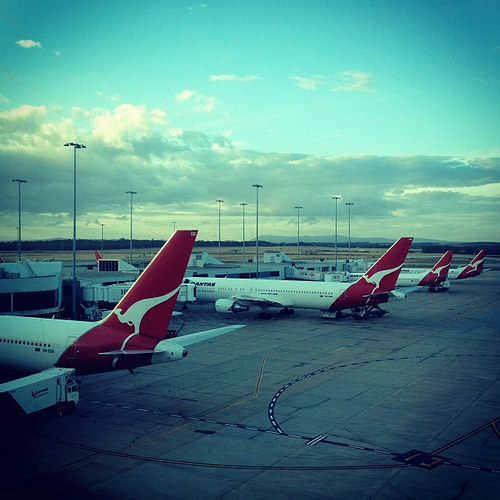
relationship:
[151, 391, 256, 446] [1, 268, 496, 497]
line on tarmac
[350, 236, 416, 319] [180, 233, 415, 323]
tail on plane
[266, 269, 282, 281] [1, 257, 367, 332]
window on building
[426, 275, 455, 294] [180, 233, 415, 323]
truck by plane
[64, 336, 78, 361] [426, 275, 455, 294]
door by truck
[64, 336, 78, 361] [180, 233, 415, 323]
door on plane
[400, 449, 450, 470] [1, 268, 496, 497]
box on tarmac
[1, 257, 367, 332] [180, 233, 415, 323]
building by plane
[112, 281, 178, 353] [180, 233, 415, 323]
logo on plane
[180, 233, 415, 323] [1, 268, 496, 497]
plane on tarmac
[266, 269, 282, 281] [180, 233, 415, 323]
window by plane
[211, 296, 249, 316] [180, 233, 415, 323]
engine on plane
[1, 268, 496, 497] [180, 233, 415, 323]
tarmac with plane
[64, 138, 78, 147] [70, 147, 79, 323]
light on pole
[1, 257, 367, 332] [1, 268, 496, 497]
building by tarmac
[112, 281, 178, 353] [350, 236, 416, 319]
logo on tail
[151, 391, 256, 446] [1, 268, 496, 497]
line over tarmac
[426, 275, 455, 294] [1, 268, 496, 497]
truck on tarmac